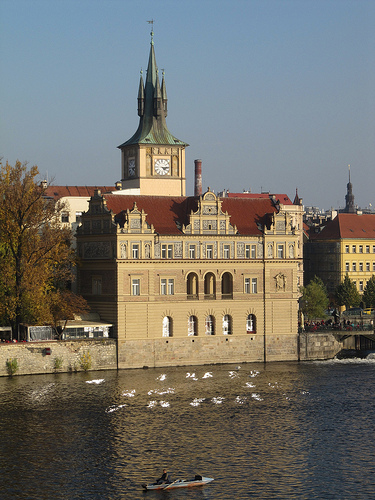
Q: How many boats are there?
A: One.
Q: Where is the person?
A: In a boat.